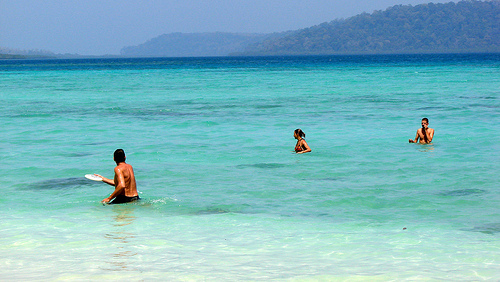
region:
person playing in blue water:
[81, 137, 154, 212]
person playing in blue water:
[273, 122, 333, 193]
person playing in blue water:
[407, 110, 439, 153]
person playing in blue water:
[6, 77, 66, 107]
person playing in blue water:
[18, 118, 88, 159]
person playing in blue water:
[9, 169, 59, 208]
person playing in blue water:
[104, 84, 171, 130]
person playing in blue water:
[198, 74, 265, 102]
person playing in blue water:
[321, 73, 359, 118]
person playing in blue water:
[195, 166, 268, 201]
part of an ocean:
[379, 206, 399, 218]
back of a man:
[126, 175, 133, 188]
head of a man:
[123, 150, 125, 160]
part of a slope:
[323, 35, 333, 43]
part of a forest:
[378, 23, 393, 33]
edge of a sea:
[198, 230, 244, 262]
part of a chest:
[416, 132, 428, 136]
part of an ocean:
[232, 122, 250, 141]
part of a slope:
[198, 45, 212, 51]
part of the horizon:
[127, 64, 133, 71]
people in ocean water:
[79, 90, 436, 211]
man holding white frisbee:
[80, 140, 136, 206]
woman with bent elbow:
[285, 125, 310, 155]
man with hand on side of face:
[405, 112, 431, 142]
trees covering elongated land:
[1, 1, 496, 59]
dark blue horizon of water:
[1, 50, 496, 66]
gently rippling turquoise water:
[10, 75, 490, 202]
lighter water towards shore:
[6, 201, 491, 273]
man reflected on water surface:
[95, 205, 137, 275]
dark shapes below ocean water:
[18, 154, 493, 239]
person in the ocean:
[79, 144, 152, 211]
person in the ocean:
[289, 123, 314, 156]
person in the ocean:
[402, 116, 436, 148]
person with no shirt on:
[81, 145, 145, 211]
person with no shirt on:
[409, 115, 436, 146]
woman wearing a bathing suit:
[289, 125, 312, 160]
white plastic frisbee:
[82, 166, 104, 184]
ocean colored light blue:
[2, 57, 499, 277]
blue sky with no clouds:
[2, 0, 424, 57]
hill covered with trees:
[225, 3, 499, 59]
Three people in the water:
[95, 113, 433, 203]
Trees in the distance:
[115, 0, 490, 65]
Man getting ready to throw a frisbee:
[80, 145, 135, 200]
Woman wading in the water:
[285, 120, 310, 155]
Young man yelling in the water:
[400, 110, 430, 145]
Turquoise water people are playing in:
[0, 65, 490, 215]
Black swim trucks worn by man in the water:
[105, 190, 135, 200]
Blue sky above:
[0, 0, 480, 50]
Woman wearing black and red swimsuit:
[289, 126, 310, 156]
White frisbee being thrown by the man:
[81, 169, 105, 185]